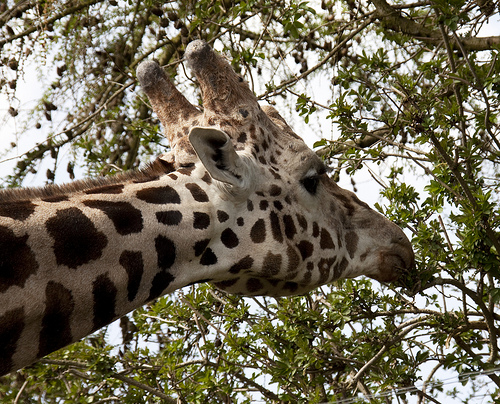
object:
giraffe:
[0, 39, 415, 377]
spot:
[136, 185, 180, 203]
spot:
[84, 199, 146, 236]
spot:
[45, 206, 110, 270]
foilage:
[374, 167, 458, 275]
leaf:
[304, 114, 309, 125]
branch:
[282, 88, 335, 113]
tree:
[0, 0, 498, 404]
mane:
[0, 157, 177, 203]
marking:
[315, 162, 328, 175]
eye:
[299, 174, 321, 196]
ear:
[187, 126, 251, 189]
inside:
[204, 136, 242, 180]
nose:
[399, 236, 416, 269]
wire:
[345, 368, 498, 403]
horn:
[186, 40, 258, 118]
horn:
[136, 60, 201, 142]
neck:
[0, 169, 222, 377]